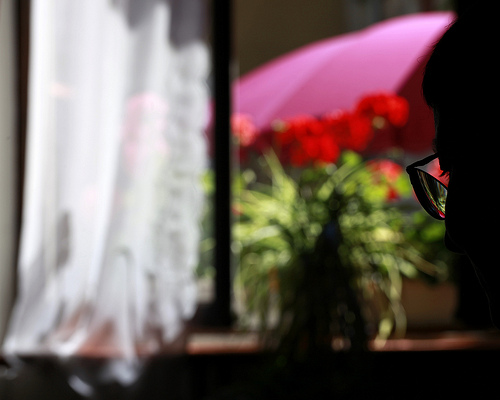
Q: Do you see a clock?
A: No, there are no clocks.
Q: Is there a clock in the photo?
A: No, there are no clocks.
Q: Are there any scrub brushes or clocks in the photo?
A: No, there are no clocks or scrub brushes.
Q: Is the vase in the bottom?
A: Yes, the vase is in the bottom of the image.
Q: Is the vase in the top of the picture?
A: No, the vase is in the bottom of the image.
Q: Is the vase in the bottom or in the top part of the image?
A: The vase is in the bottom of the image.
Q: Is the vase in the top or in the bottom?
A: The vase is in the bottom of the image.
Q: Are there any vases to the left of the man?
A: Yes, there is a vase to the left of the man.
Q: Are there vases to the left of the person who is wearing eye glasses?
A: Yes, there is a vase to the left of the man.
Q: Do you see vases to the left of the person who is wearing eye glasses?
A: Yes, there is a vase to the left of the man.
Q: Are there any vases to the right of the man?
A: No, the vase is to the left of the man.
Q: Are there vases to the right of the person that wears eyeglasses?
A: No, the vase is to the left of the man.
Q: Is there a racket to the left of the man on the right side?
A: No, there is a vase to the left of the man.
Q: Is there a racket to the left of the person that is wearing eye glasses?
A: No, there is a vase to the left of the man.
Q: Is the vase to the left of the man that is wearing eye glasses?
A: Yes, the vase is to the left of the man.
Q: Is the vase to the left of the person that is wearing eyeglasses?
A: Yes, the vase is to the left of the man.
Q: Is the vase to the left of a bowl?
A: No, the vase is to the left of the man.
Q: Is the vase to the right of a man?
A: No, the vase is to the left of a man.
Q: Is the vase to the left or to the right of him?
A: The vase is to the left of the man.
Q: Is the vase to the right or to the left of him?
A: The vase is to the left of the man.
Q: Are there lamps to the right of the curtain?
A: No, there is a vase to the right of the curtain.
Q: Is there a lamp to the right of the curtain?
A: No, there is a vase to the right of the curtain.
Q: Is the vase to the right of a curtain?
A: Yes, the vase is to the right of a curtain.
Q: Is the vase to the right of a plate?
A: No, the vase is to the right of a curtain.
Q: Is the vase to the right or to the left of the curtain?
A: The vase is to the right of the curtain.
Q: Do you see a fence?
A: No, there are no fences.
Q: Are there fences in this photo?
A: No, there are no fences.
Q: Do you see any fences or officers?
A: No, there are no fences or officers.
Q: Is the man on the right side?
A: Yes, the man is on the right of the image.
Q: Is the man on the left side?
A: No, the man is on the right of the image.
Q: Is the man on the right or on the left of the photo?
A: The man is on the right of the image.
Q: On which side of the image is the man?
A: The man is on the right of the image.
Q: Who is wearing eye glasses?
A: The man is wearing eye glasses.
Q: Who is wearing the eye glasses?
A: The man is wearing eye glasses.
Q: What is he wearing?
A: The man is wearing eye glasses.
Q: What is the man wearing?
A: The man is wearing eye glasses.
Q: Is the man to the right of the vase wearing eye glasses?
A: Yes, the man is wearing eye glasses.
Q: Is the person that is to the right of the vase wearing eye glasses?
A: Yes, the man is wearing eye glasses.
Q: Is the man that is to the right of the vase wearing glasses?
A: No, the man is wearing eye glasses.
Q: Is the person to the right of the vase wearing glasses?
A: No, the man is wearing eye glasses.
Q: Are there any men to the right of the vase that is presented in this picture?
A: Yes, there is a man to the right of the vase.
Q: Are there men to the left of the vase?
A: No, the man is to the right of the vase.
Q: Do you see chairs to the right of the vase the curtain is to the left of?
A: No, there is a man to the right of the vase.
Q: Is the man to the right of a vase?
A: Yes, the man is to the right of a vase.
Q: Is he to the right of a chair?
A: No, the man is to the right of a vase.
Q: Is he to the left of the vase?
A: No, the man is to the right of the vase.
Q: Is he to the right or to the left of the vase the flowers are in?
A: The man is to the right of the vase.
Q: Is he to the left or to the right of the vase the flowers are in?
A: The man is to the right of the vase.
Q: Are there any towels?
A: No, there are no towels.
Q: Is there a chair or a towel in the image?
A: No, there are no towels or chairs.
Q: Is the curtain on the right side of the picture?
A: No, the curtain is on the left of the image.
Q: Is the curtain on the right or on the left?
A: The curtain is on the left of the image.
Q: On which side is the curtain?
A: The curtain is on the left of the image.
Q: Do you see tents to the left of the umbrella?
A: No, there is a curtain to the left of the umbrella.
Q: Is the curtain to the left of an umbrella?
A: Yes, the curtain is to the left of an umbrella.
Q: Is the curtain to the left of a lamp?
A: No, the curtain is to the left of an umbrella.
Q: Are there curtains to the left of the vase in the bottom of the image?
A: Yes, there is a curtain to the left of the vase.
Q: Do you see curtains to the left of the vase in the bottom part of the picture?
A: Yes, there is a curtain to the left of the vase.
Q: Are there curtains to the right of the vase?
A: No, the curtain is to the left of the vase.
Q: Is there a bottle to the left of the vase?
A: No, there is a curtain to the left of the vase.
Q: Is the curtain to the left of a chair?
A: No, the curtain is to the left of the vase.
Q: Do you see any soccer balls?
A: No, there are no soccer balls.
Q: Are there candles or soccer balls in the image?
A: No, there are no soccer balls or candles.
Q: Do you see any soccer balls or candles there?
A: No, there are no soccer balls or candles.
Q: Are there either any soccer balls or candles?
A: No, there are no soccer balls or candles.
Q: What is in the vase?
A: The flowers are in the vase.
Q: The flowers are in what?
A: The flowers are in the vase.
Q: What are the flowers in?
A: The flowers are in the vase.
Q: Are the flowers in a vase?
A: Yes, the flowers are in a vase.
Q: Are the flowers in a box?
A: No, the flowers are in a vase.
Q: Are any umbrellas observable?
A: Yes, there is an umbrella.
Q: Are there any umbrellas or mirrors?
A: Yes, there is an umbrella.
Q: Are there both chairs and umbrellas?
A: No, there is an umbrella but no chairs.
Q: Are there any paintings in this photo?
A: No, there are no paintings.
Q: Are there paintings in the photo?
A: No, there are no paintings.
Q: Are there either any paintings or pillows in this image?
A: No, there are no paintings or pillows.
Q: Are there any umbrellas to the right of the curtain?
A: Yes, there is an umbrella to the right of the curtain.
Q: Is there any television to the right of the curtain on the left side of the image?
A: No, there is an umbrella to the right of the curtain.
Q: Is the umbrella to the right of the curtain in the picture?
A: Yes, the umbrella is to the right of the curtain.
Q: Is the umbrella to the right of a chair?
A: No, the umbrella is to the right of the curtain.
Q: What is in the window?
A: The frame is in the window.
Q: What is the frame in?
A: The frame is in the window.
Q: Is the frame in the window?
A: Yes, the frame is in the window.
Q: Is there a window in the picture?
A: Yes, there is a window.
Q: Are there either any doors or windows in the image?
A: Yes, there is a window.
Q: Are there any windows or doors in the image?
A: Yes, there is a window.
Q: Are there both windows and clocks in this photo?
A: No, there is a window but no clocks.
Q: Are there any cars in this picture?
A: No, there are no cars.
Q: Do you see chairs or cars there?
A: No, there are no cars or chairs.